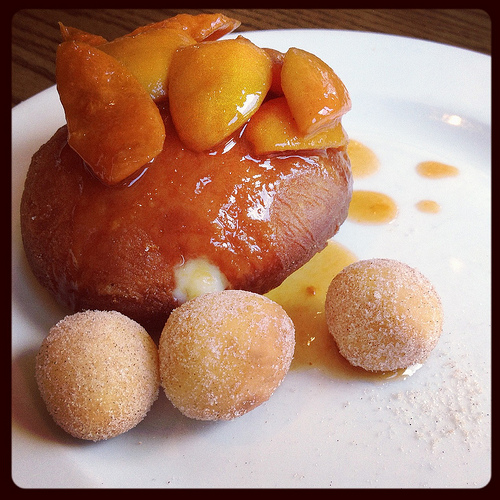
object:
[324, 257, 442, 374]
dough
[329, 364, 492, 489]
sugar crystals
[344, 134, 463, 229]
sauce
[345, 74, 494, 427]
sauceplate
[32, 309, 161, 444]
doughnuts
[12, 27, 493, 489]
plate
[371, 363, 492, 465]
sprinkle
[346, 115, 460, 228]
bad sentance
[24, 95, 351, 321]
donut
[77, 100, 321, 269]
brown syrup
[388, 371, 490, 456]
sugar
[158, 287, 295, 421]
dough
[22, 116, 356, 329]
potato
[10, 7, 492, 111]
brown table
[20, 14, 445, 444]
food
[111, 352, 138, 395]
sprinkles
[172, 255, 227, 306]
stuff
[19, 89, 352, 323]
dough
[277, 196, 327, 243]
skin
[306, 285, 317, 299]
syrup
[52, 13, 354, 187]
peaches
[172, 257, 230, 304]
cream